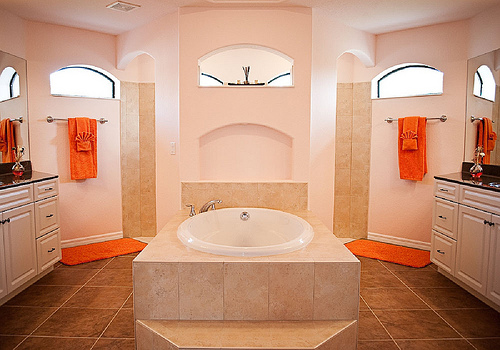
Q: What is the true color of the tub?
A: White.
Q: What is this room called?
A: Bathroom.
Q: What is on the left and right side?
A: Mirror.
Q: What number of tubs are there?
A: 1.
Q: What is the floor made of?
A: Tiles.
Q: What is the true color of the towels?
A: Orange.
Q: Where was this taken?
A: A bathroom.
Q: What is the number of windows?
A: Three.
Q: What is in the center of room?
A: A tiled tub.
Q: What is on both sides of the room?
A: Vanities.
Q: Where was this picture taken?
A: The bathroom.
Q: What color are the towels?
A: Orange.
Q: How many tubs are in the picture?
A: One.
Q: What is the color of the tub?
A: White.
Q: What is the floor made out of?
A: Tiles.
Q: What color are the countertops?
A: Black.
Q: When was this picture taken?
A: Daytime.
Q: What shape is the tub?
A: Oval.